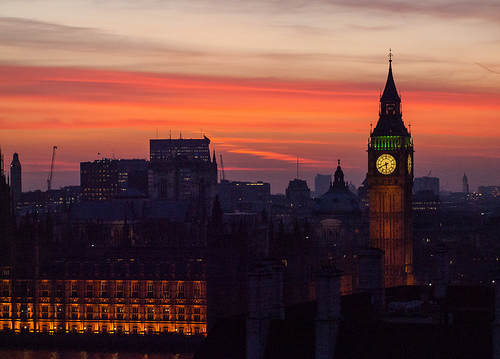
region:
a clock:
[371, 151, 395, 176]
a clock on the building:
[373, 153, 403, 175]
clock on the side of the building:
[405, 153, 416, 171]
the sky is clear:
[247, 105, 313, 125]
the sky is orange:
[213, 97, 269, 124]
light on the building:
[91, 286, 174, 336]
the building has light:
[116, 293, 174, 332]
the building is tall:
[354, 55, 433, 279]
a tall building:
[358, 65, 416, 249]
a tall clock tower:
[364, 47, 419, 287]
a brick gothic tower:
[364, 44, 416, 294]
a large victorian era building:
[1, 251, 253, 345]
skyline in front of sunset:
[5, 133, 269, 215]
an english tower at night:
[354, 53, 422, 294]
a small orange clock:
[372, 153, 399, 175]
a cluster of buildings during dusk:
[71, 124, 351, 209]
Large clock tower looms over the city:
[359, 45, 420, 310]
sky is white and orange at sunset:
[20, 13, 475, 183]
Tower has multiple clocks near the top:
[373, 153, 420, 180]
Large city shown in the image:
[0, 92, 497, 356]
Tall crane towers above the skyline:
[32, 126, 69, 206]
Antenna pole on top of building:
[290, 148, 301, 181]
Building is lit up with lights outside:
[10, 245, 239, 357]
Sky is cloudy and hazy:
[14, 10, 475, 185]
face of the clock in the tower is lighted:
[370, 149, 397, 178]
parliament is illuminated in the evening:
[71, 129, 413, 156]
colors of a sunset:
[1, 41, 497, 178]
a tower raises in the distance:
[9, 144, 21, 197]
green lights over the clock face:
[370, 124, 407, 149]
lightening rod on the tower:
[384, 45, 396, 77]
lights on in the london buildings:
[75, 164, 131, 202]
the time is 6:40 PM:
[374, 153, 396, 175]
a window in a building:
[0, 281, 12, 299]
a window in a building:
[116, 290, 126, 300]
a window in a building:
[146, 293, 159, 300]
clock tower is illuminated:
[365, 47, 415, 288]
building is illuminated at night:
[0, 50, 446, 356]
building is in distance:
[150, 135, 217, 212]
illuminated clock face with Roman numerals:
[377, 152, 394, 174]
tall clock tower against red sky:
[368, 44, 414, 288]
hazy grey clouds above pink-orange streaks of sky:
[10, 10, 357, 125]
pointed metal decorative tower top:
[383, 46, 396, 66]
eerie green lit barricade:
[367, 131, 411, 149]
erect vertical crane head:
[43, 142, 60, 187]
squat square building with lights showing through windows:
[77, 156, 147, 206]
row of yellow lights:
[245, 179, 265, 189]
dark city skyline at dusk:
[65, 74, 365, 244]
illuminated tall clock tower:
[351, 41, 424, 296]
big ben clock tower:
[350, 40, 427, 301]